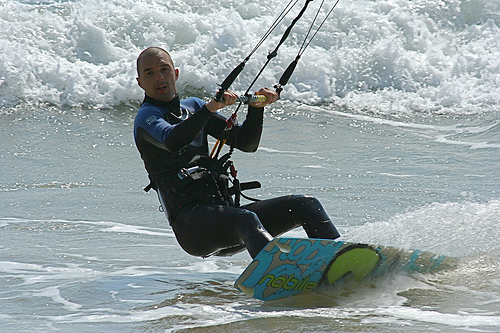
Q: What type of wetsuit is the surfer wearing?
A: Black and blue.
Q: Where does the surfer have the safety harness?
A: On his waist.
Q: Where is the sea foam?
A: Behind the surfer.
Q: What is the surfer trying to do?
A: Tip the surfboard backwards.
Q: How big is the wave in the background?
A: Large.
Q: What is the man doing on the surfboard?
A: Surfing.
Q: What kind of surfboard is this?
A: Blue and green.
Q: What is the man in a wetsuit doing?
A: Surfing.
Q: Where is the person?
A: At the ocean.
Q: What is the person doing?
A: Parasailing.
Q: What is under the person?
A: A board.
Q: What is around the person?
A: Water.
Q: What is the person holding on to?
A: A rope.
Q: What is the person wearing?
A: A wetsuit.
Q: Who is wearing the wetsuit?
A: The surfer.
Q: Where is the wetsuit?
A: On the surfer.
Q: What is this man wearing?
A: A wetsuit.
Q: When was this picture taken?
A: Daytime.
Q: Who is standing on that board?
A: The man.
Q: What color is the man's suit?
A: Black and blue.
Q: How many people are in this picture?
A: 1.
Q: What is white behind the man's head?
A: Waves crashing.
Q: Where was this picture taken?
A: The ocean.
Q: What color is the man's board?
A: Blue, green and gray.